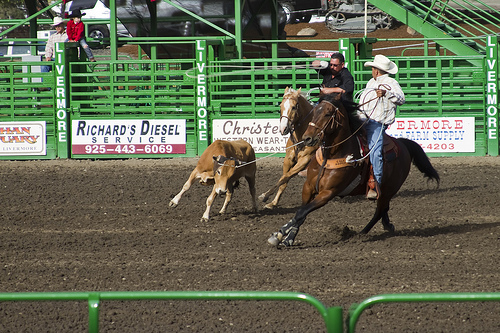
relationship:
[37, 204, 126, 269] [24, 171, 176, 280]
dirt on ground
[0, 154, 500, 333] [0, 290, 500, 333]
dirt in between metal fence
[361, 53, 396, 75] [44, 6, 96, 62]
hat on boy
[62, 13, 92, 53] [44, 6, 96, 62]
shirt on boy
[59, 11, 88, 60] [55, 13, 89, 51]
boy in shirt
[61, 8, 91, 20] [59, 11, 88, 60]
hat on boy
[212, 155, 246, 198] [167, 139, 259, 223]
head on bull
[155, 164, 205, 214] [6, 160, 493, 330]
cows leg off ground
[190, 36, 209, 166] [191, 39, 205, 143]
pole with letters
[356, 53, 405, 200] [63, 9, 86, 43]
cowboy with shirt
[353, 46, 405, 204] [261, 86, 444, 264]
cowboy riding horse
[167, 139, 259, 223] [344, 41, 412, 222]
bull being roped by cowboy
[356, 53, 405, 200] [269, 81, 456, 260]
cowboy on horse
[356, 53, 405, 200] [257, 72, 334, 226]
cowboy on horse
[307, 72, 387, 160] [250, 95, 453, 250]
reigns on horse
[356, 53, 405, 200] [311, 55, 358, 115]
cowboy in shirt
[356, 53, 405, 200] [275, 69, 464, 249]
cowboy on horse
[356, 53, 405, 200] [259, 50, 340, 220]
cowboy on horse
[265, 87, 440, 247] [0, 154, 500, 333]
horse riding on dirt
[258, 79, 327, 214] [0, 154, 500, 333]
horse riding on dirt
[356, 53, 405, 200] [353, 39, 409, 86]
cowboy wearing cowboy hat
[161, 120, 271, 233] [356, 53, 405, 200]
bull being pulled by cowboy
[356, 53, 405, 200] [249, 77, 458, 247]
cowboy on horse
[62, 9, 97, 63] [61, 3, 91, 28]
boy in a cowboy hat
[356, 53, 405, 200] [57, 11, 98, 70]
cowboy holding boy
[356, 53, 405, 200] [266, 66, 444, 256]
cowboy riding horse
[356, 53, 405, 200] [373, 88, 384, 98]
cowboy has hand